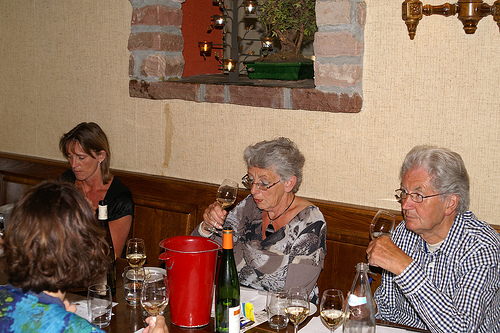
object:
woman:
[191, 135, 327, 294]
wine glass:
[203, 179, 237, 233]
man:
[369, 147, 499, 332]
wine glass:
[369, 207, 394, 264]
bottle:
[215, 226, 239, 332]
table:
[1, 271, 383, 332]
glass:
[84, 285, 111, 329]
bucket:
[158, 236, 218, 327]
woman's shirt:
[0, 282, 104, 332]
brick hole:
[165, 0, 315, 88]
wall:
[2, 0, 498, 213]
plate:
[122, 267, 167, 282]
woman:
[58, 121, 132, 258]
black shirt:
[60, 171, 137, 223]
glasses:
[394, 189, 446, 203]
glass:
[125, 237, 147, 288]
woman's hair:
[61, 121, 112, 158]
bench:
[0, 150, 499, 313]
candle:
[204, 41, 208, 52]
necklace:
[265, 212, 277, 238]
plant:
[254, 0, 316, 56]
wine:
[371, 234, 390, 240]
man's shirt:
[372, 212, 497, 332]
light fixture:
[400, 0, 498, 41]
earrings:
[100, 162, 103, 165]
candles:
[227, 61, 233, 72]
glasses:
[239, 174, 280, 191]